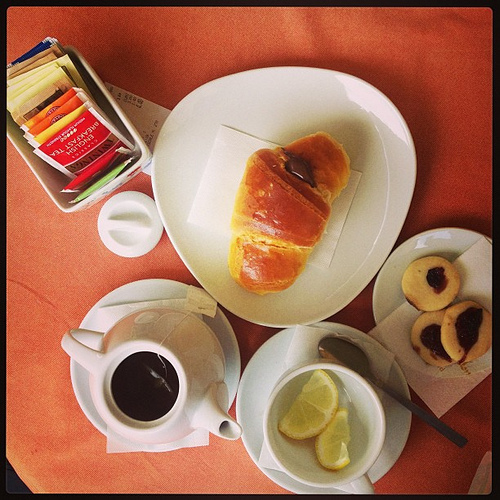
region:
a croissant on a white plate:
[215, 118, 350, 310]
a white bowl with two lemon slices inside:
[270, 368, 374, 473]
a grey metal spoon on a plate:
[326, 327, 481, 459]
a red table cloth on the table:
[28, 434, 93, 479]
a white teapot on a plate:
[66, 300, 239, 454]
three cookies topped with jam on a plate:
[399, 247, 487, 379]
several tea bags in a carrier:
[11, 40, 160, 212]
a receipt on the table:
[103, 64, 168, 161]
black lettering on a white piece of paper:
[118, 94, 150, 115]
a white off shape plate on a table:
[150, 60, 418, 331]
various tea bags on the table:
[3, 44, 151, 209]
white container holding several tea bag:
[3, 44, 150, 216]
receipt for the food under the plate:
[98, 82, 169, 175]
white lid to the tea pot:
[96, 190, 162, 260]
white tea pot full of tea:
[61, 312, 240, 450]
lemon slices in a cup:
[281, 373, 351, 470]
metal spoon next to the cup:
[318, 338, 469, 448]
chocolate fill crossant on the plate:
[228, 135, 350, 297]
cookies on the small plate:
[397, 259, 490, 376]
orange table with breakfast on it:
[4, 5, 497, 496]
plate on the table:
[136, 61, 458, 298]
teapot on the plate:
[79, 299, 240, 450]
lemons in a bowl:
[267, 375, 368, 465]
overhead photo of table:
[0, 73, 482, 478]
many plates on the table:
[90, 46, 470, 371]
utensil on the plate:
[337, 343, 481, 452]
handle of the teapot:
[59, 313, 129, 378]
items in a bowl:
[18, 50, 123, 205]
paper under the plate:
[132, 78, 167, 130]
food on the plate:
[399, 266, 487, 358]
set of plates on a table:
[11, 26, 480, 496]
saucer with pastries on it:
[371, 223, 498, 386]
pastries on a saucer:
[405, 255, 499, 366]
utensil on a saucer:
[313, 325, 474, 445]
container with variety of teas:
[2, 23, 167, 218]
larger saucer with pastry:
[139, 63, 410, 326]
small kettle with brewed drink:
[46, 283, 242, 445]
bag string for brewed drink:
[148, 280, 226, 353]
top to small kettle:
[85, 194, 176, 257]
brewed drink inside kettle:
[128, 362, 164, 407]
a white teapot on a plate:
[60, 302, 242, 444]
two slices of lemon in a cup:
[280, 365, 350, 471]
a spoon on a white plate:
[316, 335, 466, 445]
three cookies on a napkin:
[400, 256, 490, 366]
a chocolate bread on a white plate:
[231, 126, 348, 291]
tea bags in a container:
[5, 35, 151, 210]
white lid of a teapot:
[98, 196, 164, 257]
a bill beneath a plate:
[101, 83, 168, 173]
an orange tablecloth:
[6, 11, 490, 497]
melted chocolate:
[282, 152, 316, 187]